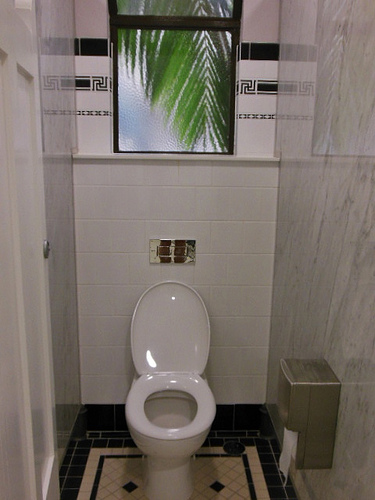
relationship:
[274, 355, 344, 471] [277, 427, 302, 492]
toilet paper holder contains paper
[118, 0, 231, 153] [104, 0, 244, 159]
palm tree outside of window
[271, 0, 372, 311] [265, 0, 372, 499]
wall appears to be marble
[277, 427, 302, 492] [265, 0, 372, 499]
toilet paper hangs on wall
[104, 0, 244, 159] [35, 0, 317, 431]
window on wall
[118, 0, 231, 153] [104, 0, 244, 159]
palm tree seen through window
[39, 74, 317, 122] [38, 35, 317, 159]
pattern on wall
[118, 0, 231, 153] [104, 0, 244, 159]
palm leaf outside of window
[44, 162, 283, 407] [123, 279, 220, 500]
tile wall behind toilet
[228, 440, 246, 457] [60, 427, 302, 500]
drain in floor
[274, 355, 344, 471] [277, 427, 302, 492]
toilet paper holder holds paper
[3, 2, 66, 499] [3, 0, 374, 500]
white door on bathroom stall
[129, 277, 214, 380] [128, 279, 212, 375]
lid in up position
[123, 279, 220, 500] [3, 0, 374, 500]
toilet in bathroom stall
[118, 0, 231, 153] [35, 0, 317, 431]
reflection on wall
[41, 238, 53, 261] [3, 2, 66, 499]
lock on stall door